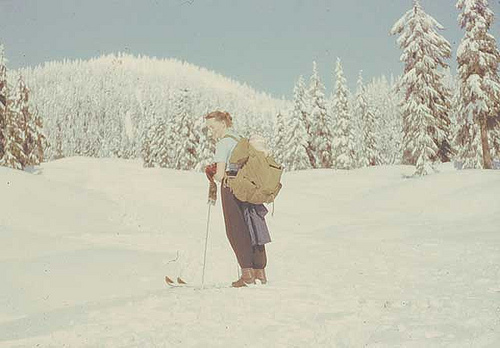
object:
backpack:
[221, 133, 283, 217]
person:
[204, 110, 266, 287]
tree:
[392, 0, 461, 168]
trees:
[165, 85, 201, 171]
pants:
[221, 176, 266, 287]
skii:
[164, 275, 287, 287]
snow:
[247, 298, 302, 326]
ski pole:
[201, 171, 215, 286]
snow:
[455, 192, 499, 221]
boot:
[231, 268, 255, 286]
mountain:
[3, 53, 291, 170]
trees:
[0, 52, 51, 170]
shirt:
[214, 128, 242, 172]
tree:
[445, 0, 499, 171]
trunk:
[479, 112, 492, 170]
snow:
[449, 305, 499, 337]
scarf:
[206, 164, 219, 207]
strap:
[271, 195, 276, 214]